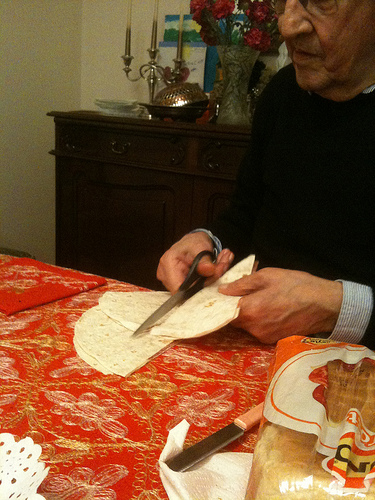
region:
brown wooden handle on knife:
[225, 407, 252, 431]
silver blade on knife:
[161, 420, 239, 476]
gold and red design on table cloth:
[25, 376, 180, 468]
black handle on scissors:
[179, 247, 212, 299]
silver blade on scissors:
[129, 286, 181, 341]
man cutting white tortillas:
[74, 268, 268, 365]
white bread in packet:
[256, 440, 309, 478]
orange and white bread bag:
[279, 336, 343, 411]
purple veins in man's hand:
[246, 291, 309, 326]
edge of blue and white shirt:
[333, 277, 362, 328]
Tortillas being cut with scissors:
[72, 254, 261, 377]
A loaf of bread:
[257, 333, 373, 495]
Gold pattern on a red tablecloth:
[15, 375, 162, 456]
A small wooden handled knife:
[159, 391, 262, 474]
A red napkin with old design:
[0, 251, 107, 316]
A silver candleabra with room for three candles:
[107, 0, 195, 113]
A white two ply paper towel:
[159, 420, 255, 499]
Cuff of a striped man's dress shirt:
[315, 273, 374, 346]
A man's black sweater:
[198, 56, 374, 307]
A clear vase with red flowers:
[189, 0, 282, 129]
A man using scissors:
[82, 0, 373, 396]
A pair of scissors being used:
[127, 242, 229, 350]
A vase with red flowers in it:
[185, 1, 281, 134]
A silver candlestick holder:
[108, 45, 185, 116]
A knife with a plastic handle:
[160, 386, 271, 494]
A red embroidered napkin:
[2, 246, 110, 344]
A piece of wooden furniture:
[35, 101, 258, 291]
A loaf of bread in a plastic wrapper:
[235, 331, 373, 498]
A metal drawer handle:
[99, 134, 135, 169]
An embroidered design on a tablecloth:
[23, 378, 161, 464]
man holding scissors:
[94, 4, 373, 340]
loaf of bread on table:
[260, 328, 374, 498]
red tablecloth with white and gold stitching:
[1, 253, 368, 498]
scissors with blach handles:
[130, 249, 217, 335]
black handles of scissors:
[181, 244, 220, 294]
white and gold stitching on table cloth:
[3, 258, 273, 491]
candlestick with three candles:
[114, 2, 192, 108]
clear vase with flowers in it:
[193, 1, 271, 137]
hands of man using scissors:
[156, 231, 340, 355]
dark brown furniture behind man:
[42, 101, 260, 292]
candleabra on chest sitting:
[119, 6, 196, 84]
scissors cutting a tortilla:
[118, 243, 233, 338]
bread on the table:
[256, 324, 366, 499]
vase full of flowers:
[190, 2, 279, 127]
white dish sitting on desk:
[84, 93, 151, 120]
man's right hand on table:
[230, 256, 338, 341]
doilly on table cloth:
[4, 423, 51, 498]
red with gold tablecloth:
[45, 382, 122, 454]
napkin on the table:
[0, 251, 114, 315]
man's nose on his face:
[278, 2, 313, 41]